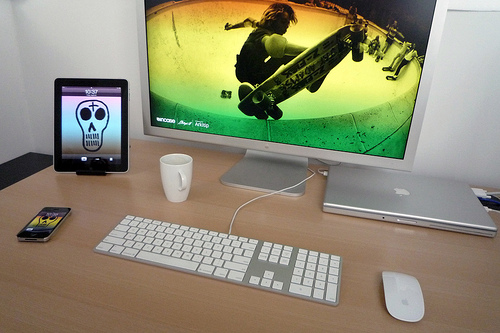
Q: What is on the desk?
A: Computer.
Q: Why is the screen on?
A: To use.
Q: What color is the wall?
A: White.